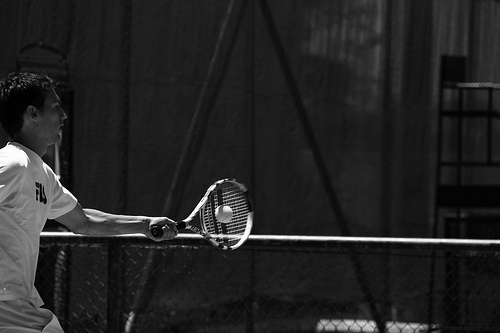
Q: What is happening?
A: Tennis.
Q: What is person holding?
A: A tennis racket.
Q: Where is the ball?
A: In middle of racket.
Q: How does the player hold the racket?
A: With left hand.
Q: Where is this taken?
A: Tennis court.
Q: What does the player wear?
A: A white tee shirt.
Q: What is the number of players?
A: One.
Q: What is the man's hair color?
A: Brunette.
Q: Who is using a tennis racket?
A: A man.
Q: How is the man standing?
A: With hand stretched out.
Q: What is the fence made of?
A: Chain.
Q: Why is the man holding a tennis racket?
A: Playing tennis.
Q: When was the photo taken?
A: Tennis match.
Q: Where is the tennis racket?
A: In player's hand.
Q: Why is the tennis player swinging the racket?
A: To hit ball.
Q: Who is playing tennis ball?
A: Young man.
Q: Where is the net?
A: Across tennis court.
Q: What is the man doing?
A: Playing tennis.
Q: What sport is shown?
A: Tennis.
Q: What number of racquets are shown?
A: 1.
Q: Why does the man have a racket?
A: He's playing tennis.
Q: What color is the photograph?
A: Black and white.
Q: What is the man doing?
A: Playing tennis.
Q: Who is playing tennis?
A: A man.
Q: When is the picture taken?
A: During the day.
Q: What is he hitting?
A: A ball.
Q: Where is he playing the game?
A: On a tennis court.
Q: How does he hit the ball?
A: With a racket.